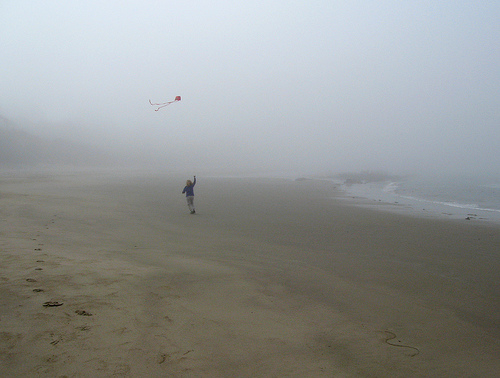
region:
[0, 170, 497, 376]
the sand on the ground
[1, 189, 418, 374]
the marks on the sand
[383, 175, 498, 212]
the body of water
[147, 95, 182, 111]
the kite in the sky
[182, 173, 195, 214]
the person flying the kite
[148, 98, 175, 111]
the tail on the kite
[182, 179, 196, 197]
the long sleeved top on the person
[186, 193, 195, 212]
the pants on the person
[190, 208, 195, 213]
the shoes on the person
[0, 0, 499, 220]
the visible thick fog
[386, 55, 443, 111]
a foggy blue sky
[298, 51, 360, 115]
a foggy blue sky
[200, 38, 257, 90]
a foggy blue sky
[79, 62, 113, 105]
a foggy blue sky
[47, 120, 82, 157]
a foggy blue sky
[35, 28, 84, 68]
a foggy blue sky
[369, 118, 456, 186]
a foggy blue sky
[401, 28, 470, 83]
a foggy blue sky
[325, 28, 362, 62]
a foggy blue sky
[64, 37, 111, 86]
a foggy blue sky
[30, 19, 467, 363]
this is along a coast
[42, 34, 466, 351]
this is a beach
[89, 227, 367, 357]
the ground here is sandy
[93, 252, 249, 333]
the sandy is black and brown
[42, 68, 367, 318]
it is very foggy here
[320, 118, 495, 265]
this is the ocean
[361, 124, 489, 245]
the ocean is blue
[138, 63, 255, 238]
the person is flying a kite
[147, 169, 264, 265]
this is a person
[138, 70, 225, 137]
the kite is red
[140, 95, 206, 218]
boy flying a kite on beach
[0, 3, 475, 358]
foggy weather on beach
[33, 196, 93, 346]
footsteps in the sand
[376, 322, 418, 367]
squiggly line in sans at right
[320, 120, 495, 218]
the ocean at right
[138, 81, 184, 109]
red kite in air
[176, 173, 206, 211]
little boy is holding kite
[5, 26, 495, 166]
sky is hazy and foggy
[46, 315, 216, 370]
foot imprints on the sand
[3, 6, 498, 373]
boy is the only person on beach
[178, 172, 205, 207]
this is a boy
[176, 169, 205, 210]
the boy is playing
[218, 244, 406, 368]
this is the beach sand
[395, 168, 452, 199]
this is the sea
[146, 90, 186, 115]
this is the kite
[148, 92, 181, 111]
the kite is red in color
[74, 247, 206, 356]
the sand is brown in color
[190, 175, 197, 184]
this is the hand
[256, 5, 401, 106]
this is the sky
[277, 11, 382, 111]
the sky is clear